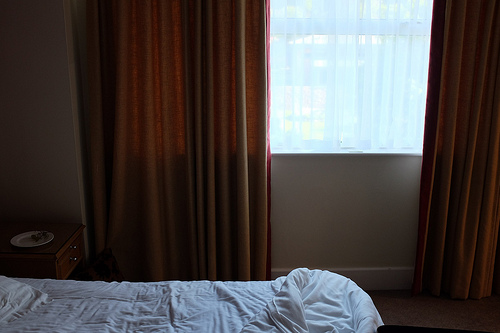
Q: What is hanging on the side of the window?
A: Curtains.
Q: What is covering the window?
A: A sheer.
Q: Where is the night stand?
A: In the corner.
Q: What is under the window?
A: The wall.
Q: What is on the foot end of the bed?
A: Blankets.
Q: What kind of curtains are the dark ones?
A: Semi-sheer.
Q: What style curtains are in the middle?
A: Sheer.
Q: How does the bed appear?
A: Unmade.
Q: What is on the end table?
A: Plate.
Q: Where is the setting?
A: Hotel room.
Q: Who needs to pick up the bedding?
A: Maid.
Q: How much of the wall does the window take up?
A: Two-thirds.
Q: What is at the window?
A: A brown curtain.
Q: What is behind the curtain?
A: A window.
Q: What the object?
A: A bed.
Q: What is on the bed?
A: A white sheet.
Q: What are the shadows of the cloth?
A: The folds of the curtain.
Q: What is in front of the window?
A: A white sheer.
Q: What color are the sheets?
A: White.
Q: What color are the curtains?
A: Red.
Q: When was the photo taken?
A: During the day.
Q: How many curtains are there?
A: Two.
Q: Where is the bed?
A: Left side.